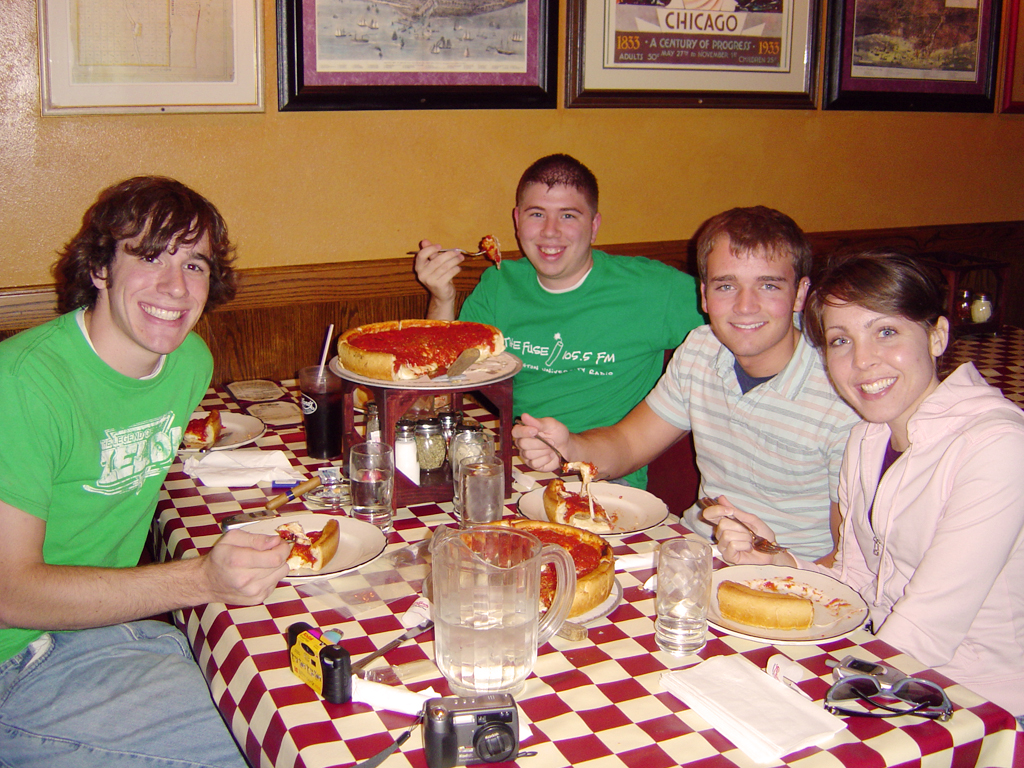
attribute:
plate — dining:
[182, 408, 262, 448]